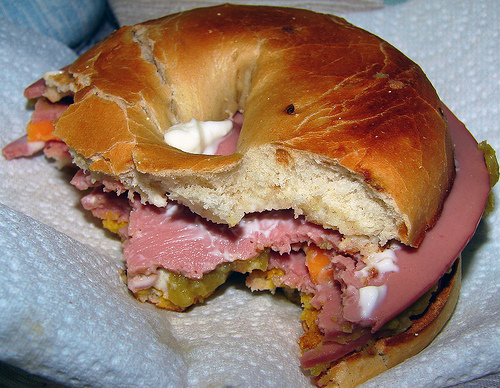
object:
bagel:
[0, 0, 499, 388]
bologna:
[22, 63, 492, 333]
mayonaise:
[164, 116, 232, 157]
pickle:
[163, 249, 270, 308]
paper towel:
[0, 1, 500, 387]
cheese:
[25, 121, 55, 141]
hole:
[160, 100, 249, 158]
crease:
[128, 23, 182, 123]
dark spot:
[350, 90, 421, 140]